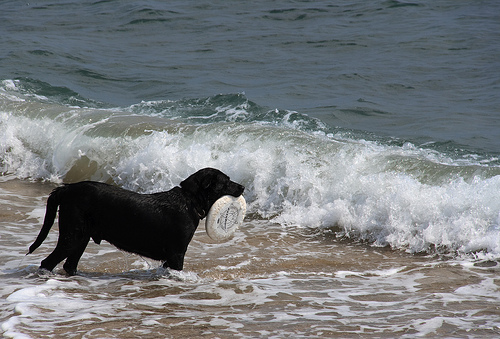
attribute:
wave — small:
[3, 73, 499, 273]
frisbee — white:
[205, 187, 247, 244]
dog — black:
[26, 165, 244, 275]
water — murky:
[257, 6, 484, 277]